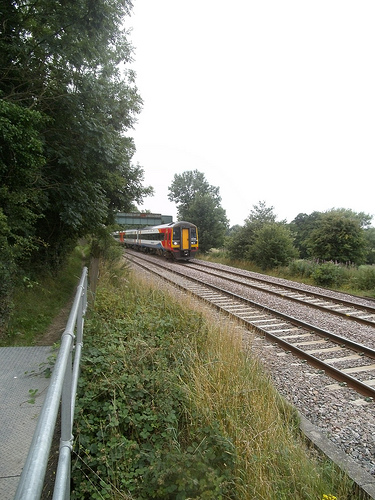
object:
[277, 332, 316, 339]
railroad tie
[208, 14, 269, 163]
floor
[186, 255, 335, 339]
train tracks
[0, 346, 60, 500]
pavement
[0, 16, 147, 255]
leaves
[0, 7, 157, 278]
tree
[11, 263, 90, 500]
silver railing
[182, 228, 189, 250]
door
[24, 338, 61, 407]
leaves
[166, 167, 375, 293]
trees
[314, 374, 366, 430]
pebbles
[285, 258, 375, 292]
bush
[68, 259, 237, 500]
shrub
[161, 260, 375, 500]
track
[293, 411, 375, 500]
barrier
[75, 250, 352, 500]
grass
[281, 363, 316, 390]
gravel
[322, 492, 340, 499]
cluster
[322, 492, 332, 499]
flower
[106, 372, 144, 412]
clover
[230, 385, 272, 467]
weeds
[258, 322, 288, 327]
railroad tie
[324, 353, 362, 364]
railroad tie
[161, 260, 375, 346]
gravel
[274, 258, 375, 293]
bushes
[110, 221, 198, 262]
front car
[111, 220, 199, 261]
passenger train